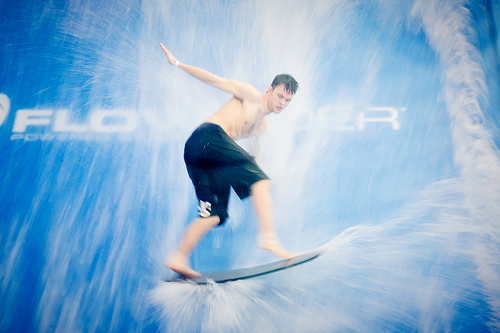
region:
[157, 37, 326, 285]
Young male surfer riding a wave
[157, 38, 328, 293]
Surfer catching a wave in a tournament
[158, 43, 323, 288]
Man balancing on surfboard.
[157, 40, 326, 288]
Young surfing professional competing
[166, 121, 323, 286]
Blue swim shorts modeled by surfer.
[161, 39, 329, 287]
Young man balancing on simulated wave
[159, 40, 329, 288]
Athletic teen in blue shorts surfing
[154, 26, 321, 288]
Professional surfer competing on blue surfboard.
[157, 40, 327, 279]
Professional surfer balancing on a splash wave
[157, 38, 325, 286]
Young surfer competing in surf competition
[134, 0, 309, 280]
this is a person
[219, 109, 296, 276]
a leg of a person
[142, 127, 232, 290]
a leg of a person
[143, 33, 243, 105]
a hand of a person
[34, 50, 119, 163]
the sky is clear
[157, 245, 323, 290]
black surfboard in blue water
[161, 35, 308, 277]
white shirtless boy on surfboard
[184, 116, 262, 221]
dark blue shorts on boy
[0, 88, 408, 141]
white advertisment letters on blue background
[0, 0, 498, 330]
burst of white water under surfer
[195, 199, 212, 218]
white logo on blue shorts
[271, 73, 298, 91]
dark hair on white boy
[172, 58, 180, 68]
white wristband on boy's right wrist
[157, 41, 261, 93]
boy's right arm extended over water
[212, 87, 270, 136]
boy's bear chest with ribcage outlined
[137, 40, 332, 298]
man on a small surfboard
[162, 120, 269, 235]
person wearing bllue swim trunks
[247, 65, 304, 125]
person with short brown wet hair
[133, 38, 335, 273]
man's arms out for balance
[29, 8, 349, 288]
water spraying down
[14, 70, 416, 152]
white lettering on blue background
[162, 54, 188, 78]
white bracelet on man's wrist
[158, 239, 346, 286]
small blue surfboard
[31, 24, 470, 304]
photograph of indoor surfing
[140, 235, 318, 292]
man barefoot on surfboard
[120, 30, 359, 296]
man on a surfboard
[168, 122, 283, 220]
swim trunks on a surfer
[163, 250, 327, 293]
surfboard under a man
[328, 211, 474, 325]
water splashing from a surfboard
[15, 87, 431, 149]
sign on a wall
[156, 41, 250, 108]
right arm of a surfer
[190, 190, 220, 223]
design on swim trunks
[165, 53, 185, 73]
bracelet on a man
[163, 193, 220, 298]
left leg of a surfer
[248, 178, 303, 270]
right leg on a surfer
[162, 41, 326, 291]
A man standing on top of a surfboard.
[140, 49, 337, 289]
A man wearing black swimwear.